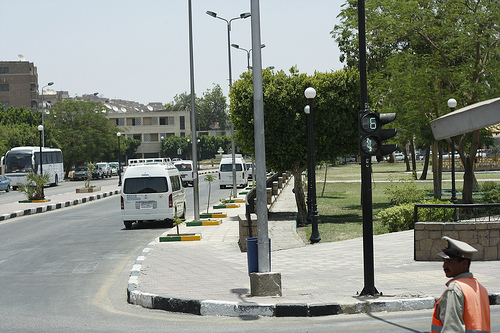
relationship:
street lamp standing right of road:
[206, 0, 251, 199] [6, 175, 231, 328]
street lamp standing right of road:
[186, 1, 199, 227] [6, 175, 231, 328]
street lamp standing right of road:
[233, 38, 264, 187] [6, 175, 231, 328]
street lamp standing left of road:
[36, 120, 48, 206] [6, 175, 231, 328]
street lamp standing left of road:
[116, 126, 123, 192] [6, 175, 231, 328]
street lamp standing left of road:
[160, 132, 167, 165] [6, 175, 231, 328]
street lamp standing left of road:
[185, 138, 190, 174] [6, 175, 231, 328]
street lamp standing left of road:
[196, 134, 202, 169] [6, 175, 231, 328]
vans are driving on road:
[122, 152, 246, 227] [6, 175, 231, 328]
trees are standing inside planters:
[24, 175, 49, 199] [20, 199, 51, 204]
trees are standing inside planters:
[169, 204, 185, 238] [161, 236, 196, 243]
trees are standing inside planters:
[201, 169, 214, 215] [202, 213, 227, 218]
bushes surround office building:
[162, 137, 231, 154] [46, 98, 193, 156]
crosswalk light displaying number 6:
[355, 107, 393, 164] [368, 115, 379, 131]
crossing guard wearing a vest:
[419, 234, 490, 331] [429, 278, 493, 332]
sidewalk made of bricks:
[145, 240, 499, 295] [177, 262, 216, 291]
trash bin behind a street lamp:
[243, 236, 277, 278] [253, 4, 270, 294]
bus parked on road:
[2, 142, 66, 191] [6, 175, 231, 328]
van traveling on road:
[122, 154, 188, 224] [6, 175, 231, 328]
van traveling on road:
[170, 157, 199, 187] [6, 175, 231, 328]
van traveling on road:
[217, 153, 247, 190] [6, 175, 231, 328]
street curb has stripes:
[124, 299, 427, 314] [153, 300, 282, 317]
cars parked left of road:
[71, 158, 121, 180] [6, 175, 231, 328]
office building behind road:
[46, 98, 193, 156] [6, 175, 231, 328]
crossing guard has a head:
[419, 234, 490, 331] [442, 256, 472, 279]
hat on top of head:
[437, 234, 480, 264] [442, 256, 472, 279]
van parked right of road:
[122, 154, 188, 224] [6, 175, 231, 328]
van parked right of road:
[217, 153, 247, 190] [6, 175, 231, 328]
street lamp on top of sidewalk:
[253, 4, 270, 294] [145, 240, 499, 295]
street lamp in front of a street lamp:
[307, 86, 319, 248] [304, 104, 315, 244]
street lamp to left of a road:
[36, 120, 48, 206] [6, 175, 231, 328]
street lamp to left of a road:
[116, 126, 123, 192] [6, 175, 231, 328]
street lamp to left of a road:
[160, 132, 167, 165] [6, 175, 231, 328]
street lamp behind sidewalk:
[445, 94, 462, 221] [145, 240, 499, 295]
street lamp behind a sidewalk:
[307, 86, 319, 248] [145, 240, 499, 295]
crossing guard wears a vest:
[419, 234, 490, 331] [429, 278, 493, 332]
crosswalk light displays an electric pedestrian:
[355, 107, 393, 164] [366, 137, 375, 155]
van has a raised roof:
[122, 154, 188, 224] [128, 158, 174, 170]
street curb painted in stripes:
[124, 299, 427, 314] [153, 300, 282, 317]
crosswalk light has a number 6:
[355, 107, 393, 164] [368, 115, 379, 131]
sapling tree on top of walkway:
[245, 63, 354, 235] [272, 182, 296, 249]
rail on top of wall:
[416, 203, 500, 227] [416, 224, 499, 259]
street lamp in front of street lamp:
[307, 86, 319, 248] [304, 104, 315, 244]